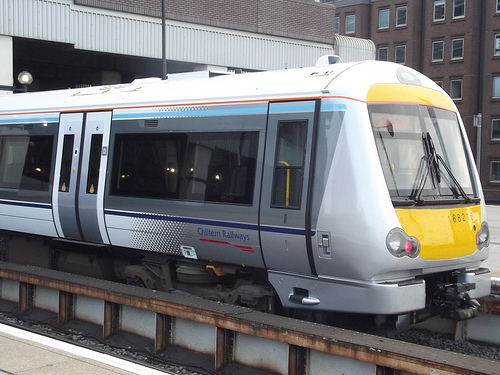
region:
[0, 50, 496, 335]
a silver grey and yellow commuter train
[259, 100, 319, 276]
a single train door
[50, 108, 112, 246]
a double train door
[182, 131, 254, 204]
a train passenger window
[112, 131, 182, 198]
a train passenger window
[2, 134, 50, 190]
a train passenger window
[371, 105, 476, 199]
a train front windshield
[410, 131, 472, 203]
train windshield wipers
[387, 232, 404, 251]
a train right headlight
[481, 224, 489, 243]
a train right headlight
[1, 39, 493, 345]
a passenger train pulling out of the station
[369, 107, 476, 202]
the windshield of a locomotive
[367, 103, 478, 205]
the windshield of an engine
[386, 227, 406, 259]
the headlight of an engine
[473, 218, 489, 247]
the headlight of an engine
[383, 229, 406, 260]
the headlight of an locomotive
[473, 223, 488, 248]
the headlight of an locomotive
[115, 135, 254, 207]
the windows of a passenger train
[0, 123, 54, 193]
the windows of a passenger train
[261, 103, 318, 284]
the door of a passenger train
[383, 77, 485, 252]
front of the train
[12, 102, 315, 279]
side of the train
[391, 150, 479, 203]
windshield wipers on train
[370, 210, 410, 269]
light on the train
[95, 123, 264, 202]
window of the train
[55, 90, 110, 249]
dors on the train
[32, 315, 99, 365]
white line on platform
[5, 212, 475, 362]
train on the track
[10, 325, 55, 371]
platform at the station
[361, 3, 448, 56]
windows on the building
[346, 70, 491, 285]
yellow paint on the front of the train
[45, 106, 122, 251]
two silver and white doors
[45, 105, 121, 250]
doors on the side of the train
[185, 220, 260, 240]
blue writing on the side of the train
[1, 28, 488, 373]
train on the tracks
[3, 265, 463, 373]
rust along the tracks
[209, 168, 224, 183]
small light glare in the window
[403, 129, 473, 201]
black windshield wipers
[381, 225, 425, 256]
lights on the front of the train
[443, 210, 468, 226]
black numbers on the front of the train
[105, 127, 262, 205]
window of a train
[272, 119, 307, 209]
window of a train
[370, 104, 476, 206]
window of a train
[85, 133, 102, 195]
window of a train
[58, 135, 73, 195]
window of a train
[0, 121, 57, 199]
window of a train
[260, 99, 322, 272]
door of a train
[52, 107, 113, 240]
the doors are closed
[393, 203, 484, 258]
the paint is yellow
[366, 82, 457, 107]
the paint is yellow